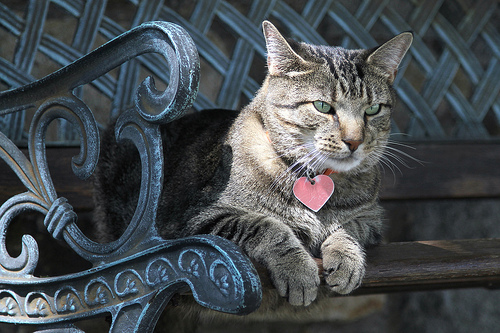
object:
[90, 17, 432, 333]
tabby cat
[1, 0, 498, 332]
bench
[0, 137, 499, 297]
seat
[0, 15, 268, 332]
arm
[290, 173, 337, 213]
tag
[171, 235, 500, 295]
slat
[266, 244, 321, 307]
paw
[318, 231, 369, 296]
paw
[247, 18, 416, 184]
head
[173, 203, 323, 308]
leg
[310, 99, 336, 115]
eye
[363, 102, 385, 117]
eye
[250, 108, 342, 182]
collar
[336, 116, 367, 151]
nose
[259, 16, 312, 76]
ear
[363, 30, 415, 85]
ear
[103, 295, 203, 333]
tail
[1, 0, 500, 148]
back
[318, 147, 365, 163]
mouth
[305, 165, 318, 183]
loop